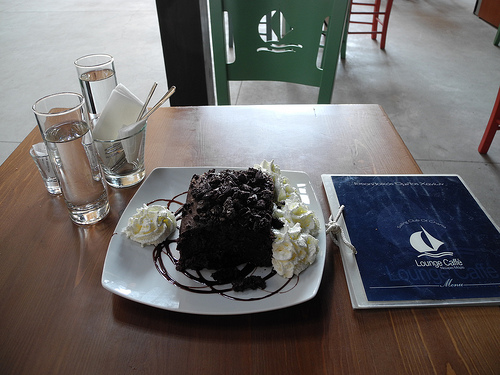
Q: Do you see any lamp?
A: No, there are no lamps.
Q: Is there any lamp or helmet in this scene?
A: No, there are no lamps or helmets.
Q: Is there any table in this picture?
A: Yes, there is a table.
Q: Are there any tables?
A: Yes, there is a table.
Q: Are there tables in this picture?
A: Yes, there is a table.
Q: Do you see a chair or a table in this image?
A: Yes, there is a table.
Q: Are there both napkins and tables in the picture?
A: Yes, there are both a table and a napkin.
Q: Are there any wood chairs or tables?
A: Yes, there is a wood table.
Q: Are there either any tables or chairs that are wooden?
A: Yes, the table is wooden.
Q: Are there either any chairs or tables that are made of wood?
A: Yes, the table is made of wood.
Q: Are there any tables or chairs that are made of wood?
A: Yes, the table is made of wood.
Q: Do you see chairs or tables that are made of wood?
A: Yes, the table is made of wood.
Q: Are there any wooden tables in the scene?
A: Yes, there is a wood table.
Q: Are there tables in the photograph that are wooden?
A: Yes, there is a table that is wooden.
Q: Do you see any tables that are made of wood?
A: Yes, there is a table that is made of wood.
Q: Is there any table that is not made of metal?
A: Yes, there is a table that is made of wood.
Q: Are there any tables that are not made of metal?
A: Yes, there is a table that is made of wood.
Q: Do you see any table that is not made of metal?
A: Yes, there is a table that is made of wood.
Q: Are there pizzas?
A: No, there are no pizzas.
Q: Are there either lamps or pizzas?
A: No, there are no pizzas or lamps.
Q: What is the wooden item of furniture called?
A: The piece of furniture is a table.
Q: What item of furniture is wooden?
A: The piece of furniture is a table.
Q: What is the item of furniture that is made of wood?
A: The piece of furniture is a table.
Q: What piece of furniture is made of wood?
A: The piece of furniture is a table.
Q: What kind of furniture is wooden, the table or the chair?
A: The table is wooden.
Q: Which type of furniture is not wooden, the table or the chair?
A: The chair is not wooden.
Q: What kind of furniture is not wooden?
A: The furniture is a chair.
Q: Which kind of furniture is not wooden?
A: The furniture is a chair.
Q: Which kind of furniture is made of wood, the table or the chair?
A: The table is made of wood.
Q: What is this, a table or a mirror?
A: This is a table.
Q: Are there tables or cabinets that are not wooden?
A: No, there is a table but it is wooden.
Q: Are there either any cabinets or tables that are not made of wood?
A: No, there is a table but it is made of wood.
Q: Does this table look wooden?
A: Yes, the table is wooden.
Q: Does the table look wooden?
A: Yes, the table is wooden.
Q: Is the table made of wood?
A: Yes, the table is made of wood.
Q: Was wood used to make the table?
A: Yes, the table is made of wood.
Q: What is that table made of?
A: The table is made of wood.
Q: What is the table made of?
A: The table is made of wood.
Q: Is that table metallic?
A: No, the table is wooden.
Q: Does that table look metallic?
A: No, the table is wooden.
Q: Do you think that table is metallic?
A: No, the table is wooden.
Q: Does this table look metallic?
A: No, the table is wooden.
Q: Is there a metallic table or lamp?
A: No, there is a table but it is wooden.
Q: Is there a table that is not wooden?
A: No, there is a table but it is wooden.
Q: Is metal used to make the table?
A: No, the table is made of wood.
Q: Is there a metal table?
A: No, there is a table but it is made of wood.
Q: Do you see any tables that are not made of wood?
A: No, there is a table but it is made of wood.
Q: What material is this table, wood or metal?
A: The table is made of wood.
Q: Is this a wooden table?
A: Yes, this is a wooden table.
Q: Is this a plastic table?
A: No, this is a wooden table.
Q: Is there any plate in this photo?
A: Yes, there is a plate.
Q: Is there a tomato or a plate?
A: Yes, there is a plate.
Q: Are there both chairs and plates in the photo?
A: Yes, there are both a plate and a chair.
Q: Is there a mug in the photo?
A: No, there are no mugs.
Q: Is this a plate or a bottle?
A: This is a plate.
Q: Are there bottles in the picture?
A: No, there are no bottles.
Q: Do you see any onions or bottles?
A: No, there are no bottles or onions.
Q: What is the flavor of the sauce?
A: That is a chocolate sauce.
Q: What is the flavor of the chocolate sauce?
A: That is a chocolate sauce.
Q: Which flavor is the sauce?
A: That is a chocolate sauce.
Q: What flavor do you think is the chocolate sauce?
A: That is a chocolate sauce.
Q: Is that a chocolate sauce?
A: Yes, that is a chocolate sauce.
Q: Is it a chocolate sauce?
A: Yes, that is a chocolate sauce.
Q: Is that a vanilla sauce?
A: No, that is a chocolate sauce.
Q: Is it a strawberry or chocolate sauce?
A: That is a chocolate sauce.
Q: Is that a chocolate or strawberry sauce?
A: That is a chocolate sauce.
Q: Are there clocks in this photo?
A: No, there are no clocks.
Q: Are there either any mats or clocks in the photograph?
A: No, there are no clocks or mats.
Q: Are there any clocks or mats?
A: No, there are no clocks or mats.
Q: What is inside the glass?
A: The water is inside the glass.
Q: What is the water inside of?
A: The water is inside the glass.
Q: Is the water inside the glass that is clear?
A: Yes, the water is inside the glass.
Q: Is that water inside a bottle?
A: No, the water is inside the glass.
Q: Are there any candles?
A: No, there are no candles.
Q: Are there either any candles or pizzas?
A: No, there are no candles or pizzas.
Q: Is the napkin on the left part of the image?
A: Yes, the napkin is on the left of the image.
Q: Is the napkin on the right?
A: No, the napkin is on the left of the image.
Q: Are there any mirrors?
A: No, there are no mirrors.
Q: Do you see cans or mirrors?
A: No, there are no mirrors or cans.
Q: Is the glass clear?
A: Yes, the glass is clear.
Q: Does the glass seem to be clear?
A: Yes, the glass is clear.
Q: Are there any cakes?
A: Yes, there is a cake.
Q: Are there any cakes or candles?
A: Yes, there is a cake.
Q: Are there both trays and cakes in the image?
A: No, there is a cake but no trays.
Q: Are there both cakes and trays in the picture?
A: No, there is a cake but no trays.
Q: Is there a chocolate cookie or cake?
A: Yes, there is a chocolate cake.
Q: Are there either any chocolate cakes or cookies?
A: Yes, there is a chocolate cake.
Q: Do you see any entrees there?
A: No, there are no entrees.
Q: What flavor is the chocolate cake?
A: This is a chocolate cake.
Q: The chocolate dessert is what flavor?
A: This is a chocolate cake.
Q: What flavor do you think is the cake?
A: This is a chocolate cake.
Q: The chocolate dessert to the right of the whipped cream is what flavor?
A: This is a chocolate cake.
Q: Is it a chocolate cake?
A: Yes, this is a chocolate cake.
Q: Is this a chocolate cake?
A: Yes, this is a chocolate cake.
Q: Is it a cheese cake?
A: No, this is a chocolate cake.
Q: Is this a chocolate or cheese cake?
A: This is a chocolate cake.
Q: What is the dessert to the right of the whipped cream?
A: The dessert is a cake.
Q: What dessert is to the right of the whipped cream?
A: The dessert is a cake.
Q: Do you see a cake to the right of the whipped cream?
A: Yes, there is a cake to the right of the whipped cream.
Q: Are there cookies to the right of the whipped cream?
A: No, there is a cake to the right of the whipped cream.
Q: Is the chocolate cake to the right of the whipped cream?
A: Yes, the cake is to the right of the whipped cream.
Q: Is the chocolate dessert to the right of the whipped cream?
A: Yes, the cake is to the right of the whipped cream.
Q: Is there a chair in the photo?
A: Yes, there is a chair.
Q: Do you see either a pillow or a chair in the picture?
A: Yes, there is a chair.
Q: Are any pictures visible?
A: No, there are no pictures.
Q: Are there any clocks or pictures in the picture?
A: No, there are no pictures or clocks.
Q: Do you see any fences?
A: No, there are no fences.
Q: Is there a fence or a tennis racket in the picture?
A: No, there are no fences or rackets.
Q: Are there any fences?
A: No, there are no fences.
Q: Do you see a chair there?
A: Yes, there is a chair.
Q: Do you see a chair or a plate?
A: Yes, there is a chair.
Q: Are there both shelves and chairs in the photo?
A: No, there is a chair but no shelves.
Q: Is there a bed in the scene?
A: No, there are no beds.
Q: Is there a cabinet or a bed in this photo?
A: No, there are no beds or cabinets.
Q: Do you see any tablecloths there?
A: No, there are no tablecloths.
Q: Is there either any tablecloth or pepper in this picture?
A: No, there are no tablecloths or peppers.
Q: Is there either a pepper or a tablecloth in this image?
A: No, there are no tablecloths or peppers.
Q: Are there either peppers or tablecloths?
A: No, there are no tablecloths or peppers.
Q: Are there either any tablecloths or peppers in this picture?
A: No, there are no tablecloths or peppers.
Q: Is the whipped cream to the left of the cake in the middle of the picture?
A: Yes, the whipped cream is to the left of the cake.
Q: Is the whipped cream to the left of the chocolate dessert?
A: Yes, the whipped cream is to the left of the cake.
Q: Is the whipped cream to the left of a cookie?
A: No, the whipped cream is to the left of the cake.